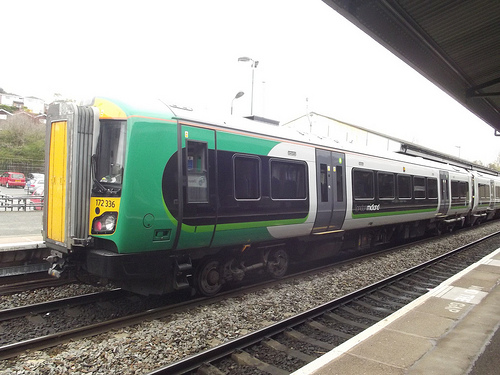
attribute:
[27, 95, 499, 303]
train — green, white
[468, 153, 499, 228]
last car — white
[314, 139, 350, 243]
doors — gray, closed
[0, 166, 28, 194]
car — red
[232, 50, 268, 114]
lamp post — illuminating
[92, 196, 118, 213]
numbers — black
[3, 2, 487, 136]
sky — cloudy